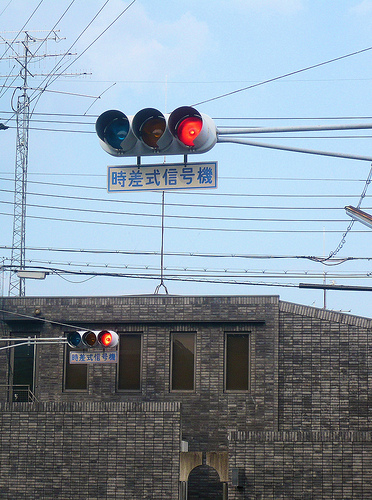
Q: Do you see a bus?
A: No, there are no buses.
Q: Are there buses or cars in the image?
A: No, there are no buses or cars.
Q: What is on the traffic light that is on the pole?
A: The sign is on the traffic signal.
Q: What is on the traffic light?
A: The sign is on the traffic signal.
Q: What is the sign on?
A: The sign is on the traffic light.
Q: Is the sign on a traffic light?
A: Yes, the sign is on a traffic light.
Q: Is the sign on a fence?
A: No, the sign is on a traffic light.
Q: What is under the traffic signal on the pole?
A: The sign is under the traffic light.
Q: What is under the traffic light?
A: The sign is under the traffic light.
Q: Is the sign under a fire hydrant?
A: No, the sign is under the traffic light.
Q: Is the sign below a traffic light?
A: Yes, the sign is below a traffic light.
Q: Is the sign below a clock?
A: No, the sign is below a traffic light.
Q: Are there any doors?
A: Yes, there is a door.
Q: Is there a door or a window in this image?
A: Yes, there is a door.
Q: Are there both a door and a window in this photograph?
A: Yes, there are both a door and a window.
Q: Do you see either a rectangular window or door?
A: Yes, there is a rectangular door.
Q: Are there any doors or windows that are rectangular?
A: Yes, the door is rectangular.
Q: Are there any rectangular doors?
A: Yes, there is a rectangular door.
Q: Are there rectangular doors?
A: Yes, there is a rectangular door.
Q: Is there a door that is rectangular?
A: Yes, there is a door that is rectangular.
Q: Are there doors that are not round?
A: Yes, there is a rectangular door.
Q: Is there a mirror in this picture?
A: No, there are no mirrors.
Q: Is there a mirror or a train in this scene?
A: No, there are no mirrors or trains.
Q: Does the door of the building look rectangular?
A: Yes, the door is rectangular.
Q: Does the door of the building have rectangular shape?
A: Yes, the door is rectangular.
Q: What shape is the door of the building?
A: The door is rectangular.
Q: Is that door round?
A: No, the door is rectangular.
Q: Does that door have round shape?
A: No, the door is rectangular.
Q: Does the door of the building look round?
A: No, the door is rectangular.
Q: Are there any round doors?
A: No, there is a door but it is rectangular.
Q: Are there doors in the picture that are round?
A: No, there is a door but it is rectangular.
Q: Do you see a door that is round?
A: No, there is a door but it is rectangular.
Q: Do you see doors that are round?
A: No, there is a door but it is rectangular.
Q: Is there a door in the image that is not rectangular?
A: No, there is a door but it is rectangular.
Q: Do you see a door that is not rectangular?
A: No, there is a door but it is rectangular.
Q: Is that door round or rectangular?
A: The door is rectangular.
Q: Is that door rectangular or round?
A: The door is rectangular.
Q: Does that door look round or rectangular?
A: The door is rectangular.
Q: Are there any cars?
A: No, there are no cars.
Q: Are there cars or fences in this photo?
A: No, there are no cars or fences.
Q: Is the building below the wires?
A: Yes, the building is below the wires.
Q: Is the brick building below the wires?
A: Yes, the building is below the wires.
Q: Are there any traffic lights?
A: Yes, there is a traffic light.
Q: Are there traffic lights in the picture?
A: Yes, there is a traffic light.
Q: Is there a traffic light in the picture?
A: Yes, there is a traffic light.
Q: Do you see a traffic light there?
A: Yes, there is a traffic light.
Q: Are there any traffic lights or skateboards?
A: Yes, there is a traffic light.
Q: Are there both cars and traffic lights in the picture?
A: No, there is a traffic light but no cars.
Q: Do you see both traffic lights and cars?
A: No, there is a traffic light but no cars.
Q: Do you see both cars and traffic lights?
A: No, there is a traffic light but no cars.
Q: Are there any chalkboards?
A: No, there are no chalkboards.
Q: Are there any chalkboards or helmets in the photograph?
A: No, there are no chalkboards or helmets.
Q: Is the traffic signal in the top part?
A: Yes, the traffic signal is in the top of the image.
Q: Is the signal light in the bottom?
A: No, the signal light is in the top of the image.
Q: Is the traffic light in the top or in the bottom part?
A: The traffic light is in the top of the image.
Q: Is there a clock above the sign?
A: No, there is a traffic light above the sign.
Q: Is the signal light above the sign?
A: Yes, the signal light is above the sign.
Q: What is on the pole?
A: The signal light is on the pole.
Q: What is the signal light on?
A: The signal light is on the pole.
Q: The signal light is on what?
A: The signal light is on the pole.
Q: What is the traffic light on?
A: The signal light is on the pole.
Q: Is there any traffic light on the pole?
A: Yes, there is a traffic light on the pole.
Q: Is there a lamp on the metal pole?
A: No, there is a traffic light on the pole.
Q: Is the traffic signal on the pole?
A: Yes, the traffic signal is on the pole.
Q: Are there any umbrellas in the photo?
A: No, there are no umbrellas.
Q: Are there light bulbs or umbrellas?
A: No, there are no umbrellas or light bulbs.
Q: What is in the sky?
A: The clouds are in the sky.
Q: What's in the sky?
A: The clouds are in the sky.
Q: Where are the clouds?
A: The clouds are in the sky.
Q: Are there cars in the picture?
A: No, there are no cars.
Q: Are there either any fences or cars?
A: No, there are no cars or fences.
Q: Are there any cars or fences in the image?
A: No, there are no cars or fences.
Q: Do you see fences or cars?
A: No, there are no cars or fences.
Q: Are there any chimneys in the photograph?
A: No, there are no chimneys.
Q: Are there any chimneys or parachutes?
A: No, there are no chimneys or parachutes.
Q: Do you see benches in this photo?
A: No, there are no benches.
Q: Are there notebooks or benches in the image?
A: No, there are no benches or notebooks.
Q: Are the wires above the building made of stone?
A: Yes, the wires are above the building.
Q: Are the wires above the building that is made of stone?
A: Yes, the wires are above the building.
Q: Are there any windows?
A: Yes, there are windows.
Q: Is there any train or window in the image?
A: Yes, there are windows.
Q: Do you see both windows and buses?
A: No, there are windows but no buses.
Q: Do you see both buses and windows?
A: No, there are windows but no buses.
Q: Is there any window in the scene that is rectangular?
A: Yes, there are rectangular windows.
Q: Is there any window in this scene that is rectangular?
A: Yes, there are windows that are rectangular.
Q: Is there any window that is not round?
A: Yes, there are rectangular windows.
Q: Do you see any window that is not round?
A: Yes, there are rectangular windows.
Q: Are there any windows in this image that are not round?
A: Yes, there are rectangular windows.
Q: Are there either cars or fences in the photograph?
A: No, there are no cars or fences.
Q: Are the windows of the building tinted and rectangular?
A: Yes, the windows are tinted and rectangular.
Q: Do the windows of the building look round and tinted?
A: No, the windows are tinted but rectangular.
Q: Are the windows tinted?
A: Yes, the windows are tinted.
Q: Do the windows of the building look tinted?
A: Yes, the windows are tinted.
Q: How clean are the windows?
A: The windows are tinted.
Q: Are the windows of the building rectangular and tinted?
A: Yes, the windows are rectangular and tinted.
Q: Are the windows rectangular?
A: Yes, the windows are rectangular.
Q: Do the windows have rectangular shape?
A: Yes, the windows are rectangular.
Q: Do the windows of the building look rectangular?
A: Yes, the windows are rectangular.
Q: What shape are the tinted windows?
A: The windows are rectangular.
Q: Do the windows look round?
A: No, the windows are rectangular.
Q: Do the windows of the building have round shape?
A: No, the windows are rectangular.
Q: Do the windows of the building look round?
A: No, the windows are rectangular.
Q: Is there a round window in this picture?
A: No, there are windows but they are rectangular.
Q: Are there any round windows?
A: No, there are windows but they are rectangular.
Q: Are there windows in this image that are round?
A: No, there are windows but they are rectangular.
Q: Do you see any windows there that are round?
A: No, there are windows but they are rectangular.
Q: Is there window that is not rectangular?
A: No, there are windows but they are rectangular.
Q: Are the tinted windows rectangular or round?
A: The windows are rectangular.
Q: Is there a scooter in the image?
A: No, there are no scooters.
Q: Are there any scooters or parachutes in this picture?
A: No, there are no scooters or parachutes.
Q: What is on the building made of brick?
A: The antenna is on the building.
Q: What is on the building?
A: The antenna is on the building.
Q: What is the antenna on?
A: The antenna is on the building.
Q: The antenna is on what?
A: The antenna is on the building.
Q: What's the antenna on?
A: The antenna is on the building.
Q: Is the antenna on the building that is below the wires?
A: Yes, the antenna is on the building.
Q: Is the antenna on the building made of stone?
A: Yes, the antenna is on the building.